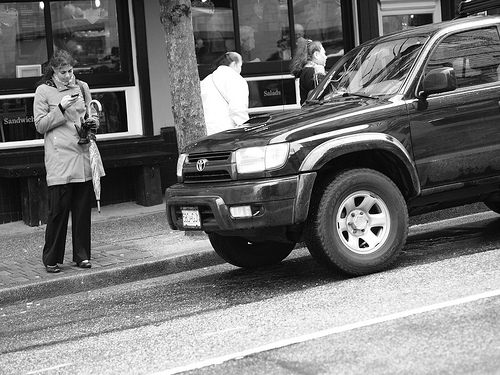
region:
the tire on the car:
[305, 159, 410, 276]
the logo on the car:
[195, 159, 205, 171]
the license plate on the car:
[180, 207, 200, 227]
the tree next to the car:
[156, 2, 217, 237]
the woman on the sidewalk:
[32, 49, 104, 273]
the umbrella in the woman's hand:
[85, 97, 106, 214]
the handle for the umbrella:
[87, 99, 102, 120]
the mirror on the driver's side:
[415, 66, 455, 108]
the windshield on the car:
[301, 32, 425, 96]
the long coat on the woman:
[32, 74, 99, 186]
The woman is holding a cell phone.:
[28, 45, 126, 287]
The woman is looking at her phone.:
[3, 40, 175, 320]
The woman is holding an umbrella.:
[26, 46, 132, 286]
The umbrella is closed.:
[77, 88, 124, 221]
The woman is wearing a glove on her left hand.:
[28, 43, 130, 284]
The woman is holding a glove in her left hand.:
[25, 40, 125, 283]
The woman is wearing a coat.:
[21, 38, 132, 310]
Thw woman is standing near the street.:
[0, 28, 260, 373]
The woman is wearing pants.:
[26, 43, 122, 295]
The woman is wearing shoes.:
[21, 42, 141, 299]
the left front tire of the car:
[316, 178, 410, 263]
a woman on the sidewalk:
[34, 55, 115, 273]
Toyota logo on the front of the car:
[189, 158, 213, 175]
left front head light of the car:
[236, 148, 282, 170]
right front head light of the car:
[169, 155, 192, 176]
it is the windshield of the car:
[335, 37, 415, 107]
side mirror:
[423, 68, 459, 93]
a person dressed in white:
[204, 49, 246, 120]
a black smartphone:
[69, 90, 82, 102]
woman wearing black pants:
[48, 184, 94, 253]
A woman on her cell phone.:
[32, 48, 116, 203]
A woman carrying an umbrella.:
[36, 45, 110, 247]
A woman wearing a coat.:
[32, 46, 124, 201]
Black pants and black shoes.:
[44, 162, 104, 274]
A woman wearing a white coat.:
[201, 42, 266, 132]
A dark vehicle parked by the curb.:
[165, 9, 497, 269]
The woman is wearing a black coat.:
[281, 34, 331, 104]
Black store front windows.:
[13, 10, 125, 72]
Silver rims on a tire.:
[320, 172, 414, 270]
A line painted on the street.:
[226, 298, 479, 338]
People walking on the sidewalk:
[197, 36, 328, 133]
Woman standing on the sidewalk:
[33, 49, 105, 274]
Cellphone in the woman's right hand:
[71, 92, 79, 99]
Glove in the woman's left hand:
[73, 116, 91, 146]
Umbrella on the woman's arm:
[86, 98, 105, 213]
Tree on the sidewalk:
[161, 2, 208, 152]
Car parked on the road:
[163, 12, 496, 274]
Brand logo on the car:
[195, 158, 207, 173]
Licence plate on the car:
[179, 208, 201, 230]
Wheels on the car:
[203, 168, 408, 276]